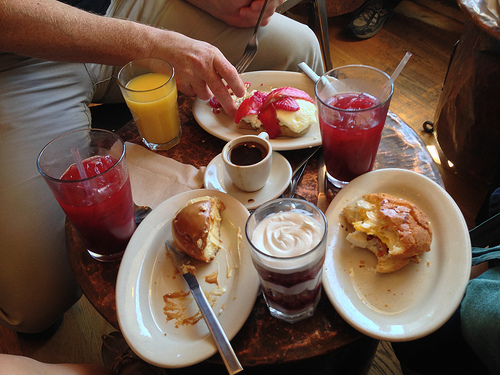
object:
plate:
[320, 167, 472, 342]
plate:
[192, 70, 350, 151]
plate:
[115, 188, 262, 369]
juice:
[123, 73, 180, 143]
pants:
[0, 1, 325, 334]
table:
[64, 69, 443, 368]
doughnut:
[172, 197, 224, 263]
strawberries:
[234, 86, 313, 138]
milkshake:
[251, 208, 325, 312]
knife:
[164, 236, 244, 374]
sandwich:
[342, 193, 432, 273]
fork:
[233, 0, 268, 74]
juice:
[56, 156, 135, 254]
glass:
[36, 127, 135, 263]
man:
[0, 0, 327, 345]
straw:
[70, 143, 92, 198]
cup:
[221, 130, 273, 191]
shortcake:
[210, 86, 317, 138]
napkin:
[107, 141, 206, 211]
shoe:
[347, 1, 389, 41]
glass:
[244, 197, 327, 322]